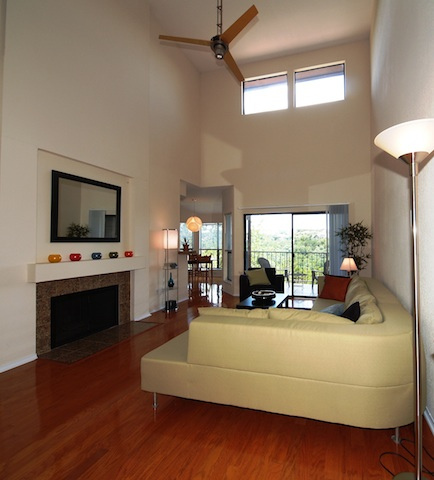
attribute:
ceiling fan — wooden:
[158, 1, 259, 84]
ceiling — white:
[154, 1, 376, 74]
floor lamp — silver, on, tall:
[375, 115, 433, 479]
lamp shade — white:
[372, 116, 433, 169]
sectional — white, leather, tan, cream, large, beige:
[139, 275, 427, 446]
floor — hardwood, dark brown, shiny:
[1, 296, 432, 479]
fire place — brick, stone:
[35, 269, 131, 357]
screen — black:
[52, 284, 120, 346]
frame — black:
[50, 168, 122, 244]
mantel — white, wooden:
[26, 253, 145, 283]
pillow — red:
[318, 273, 351, 303]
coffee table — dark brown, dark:
[236, 292, 289, 309]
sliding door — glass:
[243, 213, 328, 300]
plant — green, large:
[336, 219, 373, 277]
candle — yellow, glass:
[48, 252, 62, 264]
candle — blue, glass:
[91, 250, 103, 261]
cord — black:
[378, 435, 433, 478]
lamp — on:
[162, 225, 179, 267]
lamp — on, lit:
[338, 254, 359, 276]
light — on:
[185, 215, 203, 233]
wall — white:
[0, 0, 149, 374]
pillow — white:
[245, 267, 270, 287]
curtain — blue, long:
[325, 200, 349, 279]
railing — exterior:
[249, 250, 329, 286]